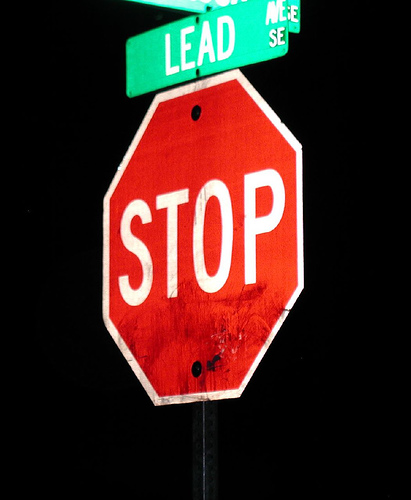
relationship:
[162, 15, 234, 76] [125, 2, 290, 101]
letters on street sign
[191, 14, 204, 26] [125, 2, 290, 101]
bolt attaches street sign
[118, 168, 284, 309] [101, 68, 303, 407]
letters on stop sign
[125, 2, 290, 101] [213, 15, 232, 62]
street sign reads letters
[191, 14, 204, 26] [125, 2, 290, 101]
bolt holds street sign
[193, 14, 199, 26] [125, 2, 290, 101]
bolt holds street sign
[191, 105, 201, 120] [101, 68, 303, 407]
bolt on stop sign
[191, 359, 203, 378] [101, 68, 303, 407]
bolt on stop sign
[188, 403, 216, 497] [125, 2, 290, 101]
pole holds street sign